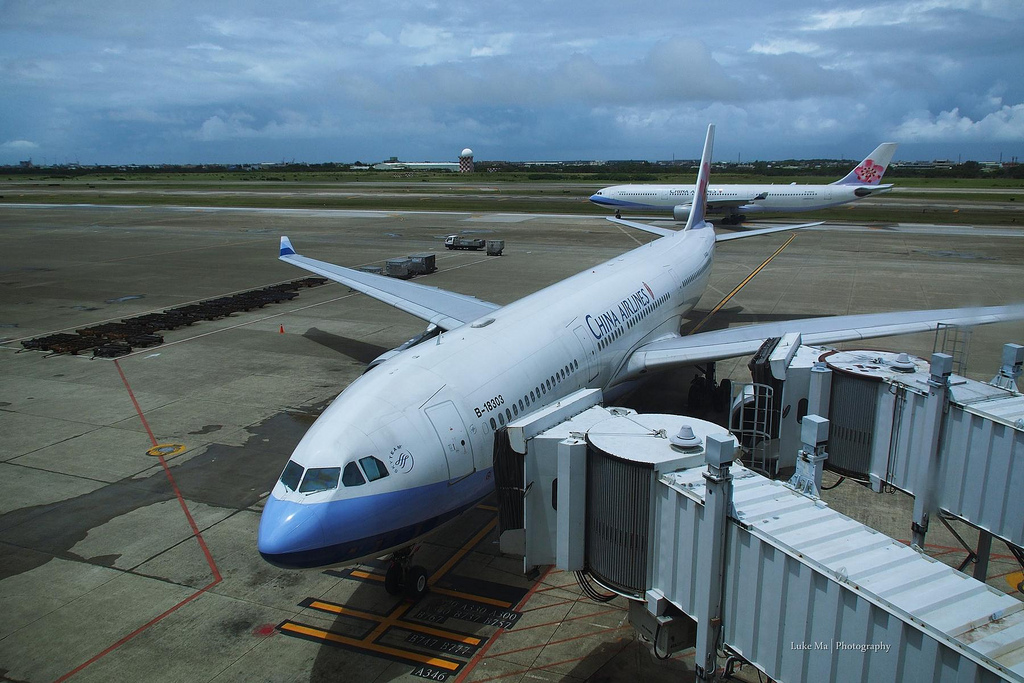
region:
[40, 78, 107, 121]
white clouds in blue sky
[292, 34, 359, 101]
white clouds in blue sky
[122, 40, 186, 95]
white clouds in blue sky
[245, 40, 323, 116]
white clouds in blue sky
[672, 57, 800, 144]
white clouds in blue sky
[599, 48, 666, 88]
white clouds in blue sky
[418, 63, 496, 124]
white clouds in blue sky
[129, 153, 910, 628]
white plane at loading gate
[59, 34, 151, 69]
white clouds in the blue sky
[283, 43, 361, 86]
white clouds in the blue sky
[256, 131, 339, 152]
white clouds in the blue sky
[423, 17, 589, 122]
white clouds in the blue sky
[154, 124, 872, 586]
white and blue plane at loading gate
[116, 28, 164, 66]
white clouds in blue sky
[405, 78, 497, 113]
white clouds in blue sky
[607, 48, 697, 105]
white clouds in blue sky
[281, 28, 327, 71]
white clouds in blue sky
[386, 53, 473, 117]
white clouds in blue sky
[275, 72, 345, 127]
white clouds in blue sky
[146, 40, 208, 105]
white clouds in blue sky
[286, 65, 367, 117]
white clouds in the blue sky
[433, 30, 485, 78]
white clouds in the blue sky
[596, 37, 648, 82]
white clouds in the blue sky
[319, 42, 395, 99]
white clouds in the blue sky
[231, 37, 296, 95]
white clouds in the blue sky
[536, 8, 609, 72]
white clouds in the blue sky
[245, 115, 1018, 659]
Plane on the ground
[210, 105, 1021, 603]
Plane is on the ground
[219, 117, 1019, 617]
Airplane on the ground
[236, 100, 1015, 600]
Airplane is on the ground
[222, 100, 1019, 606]
White and blue plane on the ground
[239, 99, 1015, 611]
White and blue airplane on the ground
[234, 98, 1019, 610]
White and blue airplane is on the ground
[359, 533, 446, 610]
Landing gear is deployed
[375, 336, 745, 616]
Landing gears are deployed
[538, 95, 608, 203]
white fluffy cloud in the sky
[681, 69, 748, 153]
white fluffy cloud in the sky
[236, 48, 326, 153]
white fluffy cloud in the sky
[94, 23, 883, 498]
this is a runway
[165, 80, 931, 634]
this is an airport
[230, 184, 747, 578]
this is a plane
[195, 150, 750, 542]
the plane is white and blue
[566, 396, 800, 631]
this is a jet way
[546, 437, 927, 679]
the jet way is a tunnel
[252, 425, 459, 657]
this is a cock pit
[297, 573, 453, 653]
the lines are yellow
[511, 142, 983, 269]
this plane is taking off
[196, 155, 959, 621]
Planes on the tarmac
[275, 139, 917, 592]
Planes at the airport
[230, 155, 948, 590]
White planes on the tarmac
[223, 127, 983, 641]
Airplanes on the tarmac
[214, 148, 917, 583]
Airplanes at the airport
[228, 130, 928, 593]
White airplanes on the tarmac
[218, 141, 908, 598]
White airplanes at the airport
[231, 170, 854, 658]
Plane on the tarmac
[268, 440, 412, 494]
Windows on the plane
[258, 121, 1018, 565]
an airplane on a runway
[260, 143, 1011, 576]
a purple and white airplane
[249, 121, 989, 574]
two airplanes in a parking lot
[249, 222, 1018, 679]
tunnel attached to an airplane